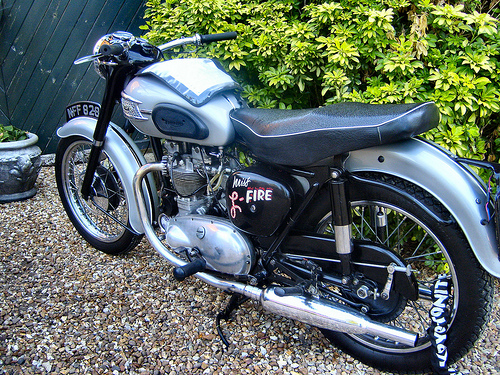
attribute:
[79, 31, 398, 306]
motorcycle — black, here, present, silver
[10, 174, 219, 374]
driveway — gravel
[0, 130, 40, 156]
plant — potted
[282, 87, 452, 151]
seat — padded, black, here, leather, large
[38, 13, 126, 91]
fence — painted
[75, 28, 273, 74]
handlebar — here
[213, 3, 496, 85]
tree — green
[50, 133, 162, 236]
wheel — black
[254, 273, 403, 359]
exhaust — silver, here, shiny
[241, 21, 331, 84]
leaves — several, green, small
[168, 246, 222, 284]
pedal — here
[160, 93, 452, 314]
motorbike — here, gray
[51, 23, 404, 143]
steering — here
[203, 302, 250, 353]
stand — here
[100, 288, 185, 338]
stones — small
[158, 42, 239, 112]
mat — here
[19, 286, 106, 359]
rocks — different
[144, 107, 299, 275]
bike — silver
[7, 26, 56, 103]
siding — wood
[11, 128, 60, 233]
planter — ceramic